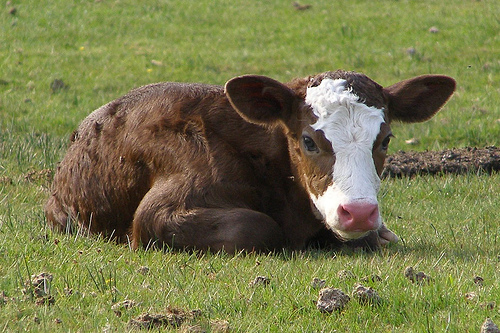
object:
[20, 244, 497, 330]
rocks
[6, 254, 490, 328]
gress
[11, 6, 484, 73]
gress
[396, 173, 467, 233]
grass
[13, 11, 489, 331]
field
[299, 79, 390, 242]
white part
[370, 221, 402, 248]
cow foot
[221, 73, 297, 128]
ear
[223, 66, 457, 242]
head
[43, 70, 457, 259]
animal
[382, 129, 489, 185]
log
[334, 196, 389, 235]
green shirt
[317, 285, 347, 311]
dead grass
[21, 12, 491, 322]
grass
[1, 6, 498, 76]
grass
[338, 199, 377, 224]
nose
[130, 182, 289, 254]
leg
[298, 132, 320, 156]
eye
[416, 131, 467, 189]
dirt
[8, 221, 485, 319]
ground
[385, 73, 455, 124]
ear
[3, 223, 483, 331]
field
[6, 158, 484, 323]
grass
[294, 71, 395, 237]
face